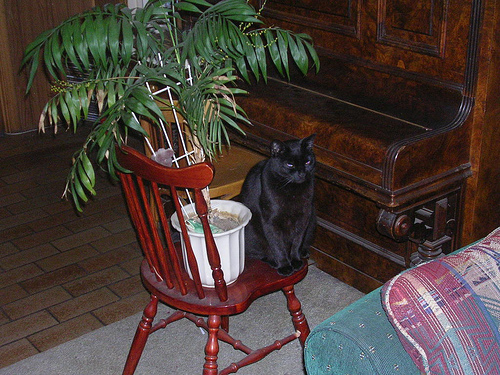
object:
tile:
[24, 311, 107, 353]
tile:
[107, 272, 147, 299]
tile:
[58, 264, 134, 299]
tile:
[49, 226, 114, 252]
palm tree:
[15, 0, 320, 224]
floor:
[0, 122, 365, 375]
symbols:
[435, 307, 440, 312]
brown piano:
[171, 2, 500, 295]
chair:
[111, 143, 312, 375]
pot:
[169, 198, 252, 289]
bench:
[138, 99, 271, 229]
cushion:
[383, 228, 498, 375]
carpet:
[0, 265, 370, 373]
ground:
[0, 142, 370, 375]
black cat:
[239, 132, 318, 276]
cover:
[213, 71, 427, 187]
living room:
[0, 0, 499, 373]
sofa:
[303, 229, 500, 375]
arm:
[302, 227, 499, 374]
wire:
[129, 107, 158, 158]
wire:
[135, 60, 198, 217]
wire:
[157, 52, 188, 155]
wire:
[186, 59, 193, 87]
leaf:
[95, 81, 104, 113]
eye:
[286, 163, 294, 168]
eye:
[305, 160, 311, 165]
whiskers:
[279, 178, 293, 189]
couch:
[302, 222, 500, 375]